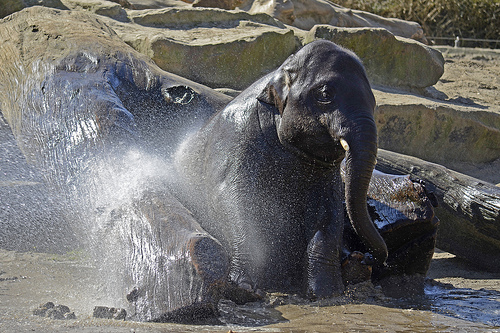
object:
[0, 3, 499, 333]
tree trunk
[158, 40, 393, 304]
elephant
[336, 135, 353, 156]
tusk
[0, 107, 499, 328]
water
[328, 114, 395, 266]
trunk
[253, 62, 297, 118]
ear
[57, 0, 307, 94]
rocks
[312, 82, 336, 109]
eye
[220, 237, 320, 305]
feet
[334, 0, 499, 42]
bushes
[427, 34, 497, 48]
guard wire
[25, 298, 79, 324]
elephant droppings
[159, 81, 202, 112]
knot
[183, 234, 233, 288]
knot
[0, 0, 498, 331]
zoo